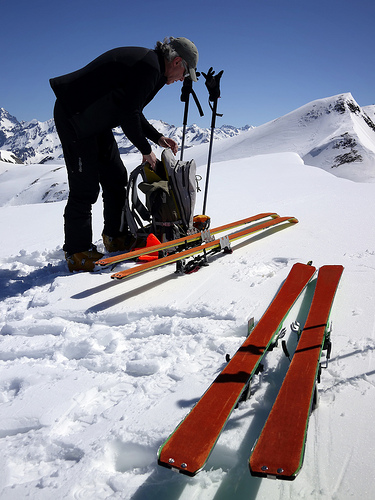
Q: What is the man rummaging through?
A: A backpack.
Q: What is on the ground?
A: Snow.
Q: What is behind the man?
A: Mountains.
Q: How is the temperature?
A: Cold.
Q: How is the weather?
A: Cold and clear.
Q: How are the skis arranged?
A: In pairs.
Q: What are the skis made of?
A: Wood.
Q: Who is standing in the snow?
A: A man with skis.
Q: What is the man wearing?
A: Black clothes.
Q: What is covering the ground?
A: Snow.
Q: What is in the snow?
A: Prints.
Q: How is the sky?
A: Clear and blue.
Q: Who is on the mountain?
A: A man.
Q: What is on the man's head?
A: A hat.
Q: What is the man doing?
A: Looking in a bag.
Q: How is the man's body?
A: Bent over.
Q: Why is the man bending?
A: To look in the bag.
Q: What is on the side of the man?
A: Ski's.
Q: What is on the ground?
A: Snow.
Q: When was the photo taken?
A: Daytime.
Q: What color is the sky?
A: Blue.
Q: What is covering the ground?
A: Snow.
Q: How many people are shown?
A: One.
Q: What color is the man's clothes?
A: Black.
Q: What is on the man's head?
A: Cap.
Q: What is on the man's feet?
A: Boots.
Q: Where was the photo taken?
A: Ski slope.